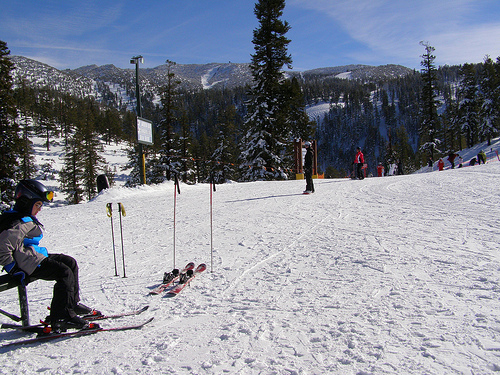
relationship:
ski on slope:
[164, 262, 207, 300] [1, 162, 500, 374]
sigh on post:
[133, 116, 157, 147] [135, 52, 148, 184]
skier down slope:
[388, 159, 395, 176] [1, 162, 500, 374]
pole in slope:
[207, 168, 217, 283] [1, 162, 500, 374]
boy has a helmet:
[0, 179, 94, 334] [13, 178, 50, 214]